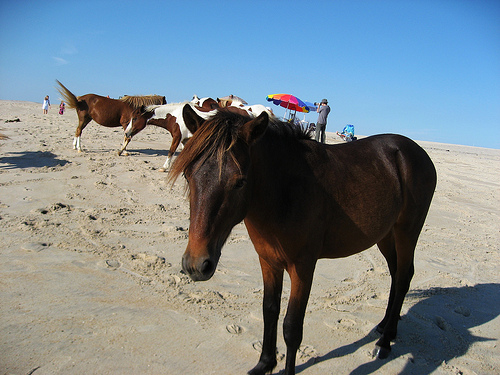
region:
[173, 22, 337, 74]
this is the sky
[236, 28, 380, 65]
the sky is blue in color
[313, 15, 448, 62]
the sky is clear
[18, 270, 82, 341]
this is the ground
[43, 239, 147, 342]
the ground is full of sand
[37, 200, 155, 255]
the ground has some tracks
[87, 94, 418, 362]
these are some horses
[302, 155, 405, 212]
the fur is black in color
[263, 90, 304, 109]
this is an umbrella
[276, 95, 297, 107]
the umbrella has several colors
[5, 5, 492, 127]
a blue sky with no clouds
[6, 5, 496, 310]
a scene outdoors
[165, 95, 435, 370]
a brown horse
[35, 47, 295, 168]
horses in the background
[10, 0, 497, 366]
a sunny day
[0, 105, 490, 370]
a sandy beach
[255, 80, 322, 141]
a multi colored umbrella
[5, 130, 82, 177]
a shadow on the left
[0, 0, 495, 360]
a scene of animals are here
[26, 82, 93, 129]
people in the background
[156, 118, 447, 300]
brown horse standing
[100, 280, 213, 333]
brown sand under horse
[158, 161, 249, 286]
head of the horse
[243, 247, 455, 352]
legs of the horse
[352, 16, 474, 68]
blue sky above the horse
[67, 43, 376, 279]
horses on the beach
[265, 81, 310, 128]
umbrella with many colors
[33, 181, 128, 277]
footprints in the sand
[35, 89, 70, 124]
people walking in the background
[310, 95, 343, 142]
man wearing the color gray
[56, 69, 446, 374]
The animals are horses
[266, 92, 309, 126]
The umbrella is rainbow colored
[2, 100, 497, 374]
The sand is tan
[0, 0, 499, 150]
Sky is clear and blue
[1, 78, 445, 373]
horses are on the beach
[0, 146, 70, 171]
Tree is casting a shadow beside horses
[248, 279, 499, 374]
Closes horse has a shadow in the sand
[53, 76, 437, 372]
The horses are brown and white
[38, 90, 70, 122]
Two people are in the distance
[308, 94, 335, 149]
The man is taking photos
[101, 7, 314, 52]
this is the sky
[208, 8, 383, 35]
the sky is blue in color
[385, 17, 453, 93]
the sky is clear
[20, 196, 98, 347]
this is the ground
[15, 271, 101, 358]
the ground is full of sand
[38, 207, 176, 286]
the ground has some tracks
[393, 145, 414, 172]
the fur is black in color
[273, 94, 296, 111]
this is an umbrella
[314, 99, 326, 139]
this is a man